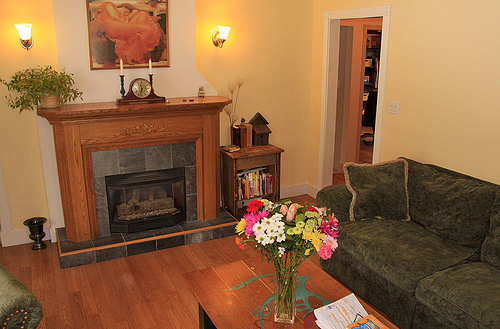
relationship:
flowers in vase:
[240, 192, 336, 259] [270, 268, 302, 324]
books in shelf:
[238, 169, 271, 194] [225, 145, 290, 228]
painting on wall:
[77, 2, 174, 74] [56, 4, 194, 92]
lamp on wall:
[211, 20, 240, 53] [56, 4, 194, 92]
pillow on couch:
[343, 156, 417, 230] [327, 152, 498, 313]